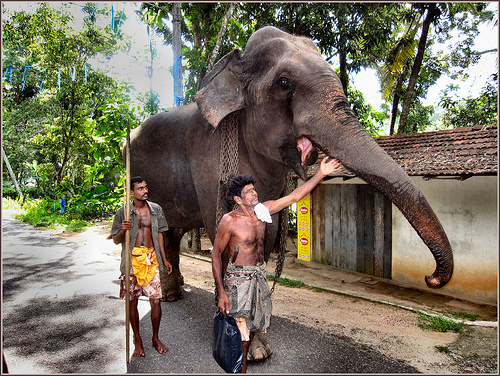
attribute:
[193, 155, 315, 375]
man — touching, carrying, dark, waist, wasite, black, holding, wearing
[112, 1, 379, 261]
elephant — open, trunk, walking, extended, head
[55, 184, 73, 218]
flag — blue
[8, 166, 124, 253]
weed — growing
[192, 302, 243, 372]
bag — black, blue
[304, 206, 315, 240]
sign — yellow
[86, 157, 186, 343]
person — holding, touching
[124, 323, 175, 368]
feet — bare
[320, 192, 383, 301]
board — building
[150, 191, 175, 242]
shirt — green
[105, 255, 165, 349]
guy — no shoes, shirtless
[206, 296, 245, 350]
string — blue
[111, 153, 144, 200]
handle — brown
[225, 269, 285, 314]
short — gray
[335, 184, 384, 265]
panel — wooden